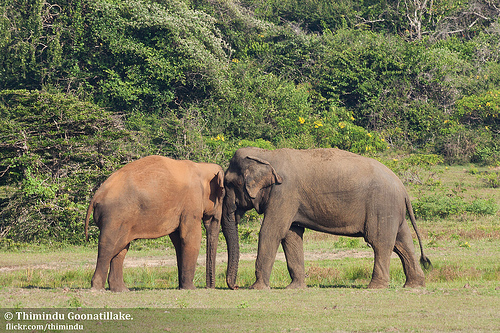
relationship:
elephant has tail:
[221, 147, 433, 290] [405, 187, 435, 271]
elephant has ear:
[221, 147, 443, 331] [238, 152, 280, 199]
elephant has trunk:
[221, 147, 433, 290] [219, 215, 238, 289]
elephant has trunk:
[83, 154, 226, 293] [205, 215, 217, 289]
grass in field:
[1, 284, 499, 331] [4, 148, 498, 331]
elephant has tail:
[221, 147, 433, 290] [405, 195, 434, 267]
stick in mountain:
[42, 114, 163, 157] [3, 0, 498, 236]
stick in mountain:
[61, 164, 109, 176] [3, 0, 498, 236]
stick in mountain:
[17, 125, 31, 152] [3, 0, 498, 236]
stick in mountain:
[50, 118, 62, 130] [3, 0, 498, 236]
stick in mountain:
[85, 104, 125, 135] [3, 0, 498, 236]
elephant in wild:
[221, 147, 433, 290] [2, 3, 497, 227]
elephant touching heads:
[221, 147, 433, 290] [199, 144, 257, 231]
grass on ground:
[313, 255, 362, 295] [140, 295, 374, 330]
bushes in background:
[5, 72, 368, 147] [3, 0, 495, 150]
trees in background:
[8, 0, 490, 172] [3, 0, 495, 150]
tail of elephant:
[403, 196, 433, 271] [221, 147, 433, 290]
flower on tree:
[315, 117, 323, 129] [195, 51, 376, 152]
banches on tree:
[366, 7, 483, 44] [2, 0, 234, 119]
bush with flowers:
[184, 66, 401, 166] [279, 102, 392, 154]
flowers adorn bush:
[291, 109, 379, 139] [235, 75, 390, 159]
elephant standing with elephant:
[50, 104, 243, 299] [194, 112, 449, 301]